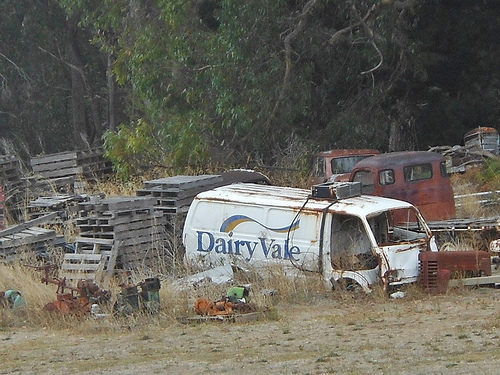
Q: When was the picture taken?
A: Daytime.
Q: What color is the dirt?
A: Brown.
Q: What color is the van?
A: White.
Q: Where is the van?
A: On the dirt.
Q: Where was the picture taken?
A: At a junkyard.